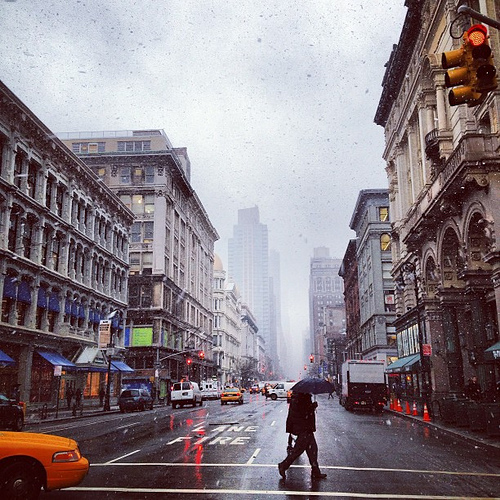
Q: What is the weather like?
A: Snowing.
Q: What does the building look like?
A: Tall with a lot of windows.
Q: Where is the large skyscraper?
A: In the distant.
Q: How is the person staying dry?
A: Carrying an umbrella.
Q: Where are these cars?
A: On city street.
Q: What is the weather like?
A: Rainy.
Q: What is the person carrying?
A: An umbrella.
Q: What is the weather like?
A: Raining.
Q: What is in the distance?
A: Tall buildings.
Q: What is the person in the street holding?
A: An umbrella.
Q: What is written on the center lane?
A: Fire lane.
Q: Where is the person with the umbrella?
A: In the crosswalk.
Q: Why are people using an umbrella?
A: It's raining.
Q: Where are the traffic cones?
A: On the sidewalk at the right.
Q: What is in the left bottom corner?
A: The front of a taxi.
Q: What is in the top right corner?
A: Traffic light.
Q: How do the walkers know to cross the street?
A: The light is red for oncoming traffic.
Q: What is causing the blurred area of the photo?
A: Fog.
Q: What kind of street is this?
A: One-way.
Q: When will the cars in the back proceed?
A: When the lights turn green.